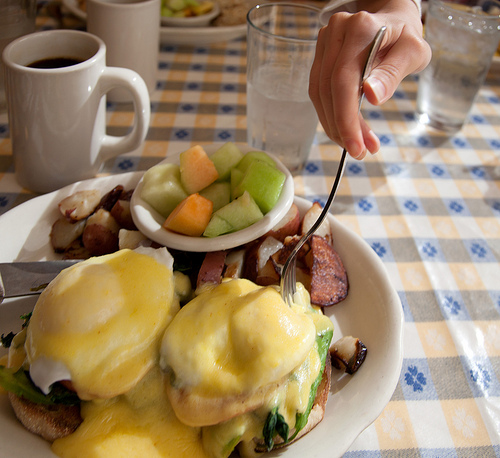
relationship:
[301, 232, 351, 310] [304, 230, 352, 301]
food of sausage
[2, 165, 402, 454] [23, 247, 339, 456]
plate full of food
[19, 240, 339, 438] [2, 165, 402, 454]
food on plate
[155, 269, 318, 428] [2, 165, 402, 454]
eggs on plate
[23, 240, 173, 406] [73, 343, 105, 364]
eggs covered with sauce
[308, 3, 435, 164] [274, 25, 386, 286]
hand holds a fork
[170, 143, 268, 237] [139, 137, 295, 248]
fruit in bowl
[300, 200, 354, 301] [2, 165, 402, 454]
potatoes on plate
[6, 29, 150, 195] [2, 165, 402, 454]
cup on plate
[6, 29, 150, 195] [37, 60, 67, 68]
cup contains coffee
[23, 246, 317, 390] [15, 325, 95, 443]
eggs on bun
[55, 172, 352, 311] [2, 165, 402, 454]
potatoes on plate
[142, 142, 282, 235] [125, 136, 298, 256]
fruit in a bowl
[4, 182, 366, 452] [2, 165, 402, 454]
food in a plate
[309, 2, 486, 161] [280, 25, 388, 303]
person holding a fork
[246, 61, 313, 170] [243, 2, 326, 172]
water in a glass